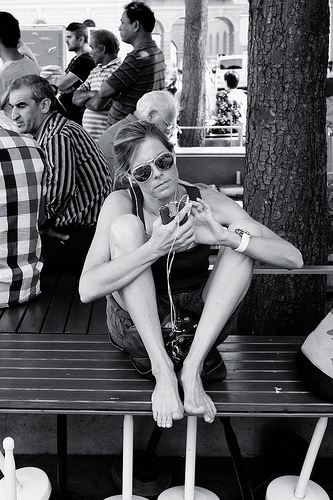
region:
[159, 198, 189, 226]
A mobile cell phone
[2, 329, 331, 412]
A large slatted bench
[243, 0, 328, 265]
A large tree trunk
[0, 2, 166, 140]
A large crowd of standing people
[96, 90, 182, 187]
A older man sitting down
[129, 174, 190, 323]
A cell phone ear piece and cord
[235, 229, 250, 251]
A wristwatch with a white band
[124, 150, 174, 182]
Large rimmed dark sunglasses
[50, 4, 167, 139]
Men standing with their arms folded in front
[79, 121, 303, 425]
A woman sitting on a bench looking at her cell phone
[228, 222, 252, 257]
shiny white watch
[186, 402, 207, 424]
woman's curled up toe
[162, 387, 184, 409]
veins on woman's foot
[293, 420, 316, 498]
long white stand with base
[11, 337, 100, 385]
wooden seating surface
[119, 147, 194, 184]
shiny black sun glasses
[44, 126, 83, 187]
long sleeve black and white shirt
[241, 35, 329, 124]
wide trunk of tree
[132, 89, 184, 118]
old man's silver hair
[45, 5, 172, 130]
men standing around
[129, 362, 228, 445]
bare feet up on the bench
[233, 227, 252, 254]
watch on the woman's arm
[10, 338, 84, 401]
wooden slatted bench around a tree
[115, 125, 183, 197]
woman wearing sunglasses sitting on a bench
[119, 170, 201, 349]
woman listening to music through headphones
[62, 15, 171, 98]
men standing with arms folded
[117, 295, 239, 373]
purse between the woman's legs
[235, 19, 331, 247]
tree surrounded by a bench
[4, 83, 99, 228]
older man in striped shirt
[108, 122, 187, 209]
woman with her hair pulled back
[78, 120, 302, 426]
the woman sitting on a bench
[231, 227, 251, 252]
the watch on the woman's wrist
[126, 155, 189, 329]
the earphones in the woman's ears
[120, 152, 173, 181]
the sunglasses on the woman's face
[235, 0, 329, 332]
the tree trunk next to the woman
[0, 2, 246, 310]
the people behind the woman sitting down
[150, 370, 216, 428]
the woman's bare feet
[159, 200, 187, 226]
the electronic device in the woman's hands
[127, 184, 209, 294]
the tank top on the woman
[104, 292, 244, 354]
the shorts on the woman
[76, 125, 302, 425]
woman sitting on a bench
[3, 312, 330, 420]
wooden bench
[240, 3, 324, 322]
tree trunk next to the woman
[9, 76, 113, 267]
old man in striped shirt sitting down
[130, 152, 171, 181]
sunglasses on the woman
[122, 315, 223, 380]
the woman's purse under her legs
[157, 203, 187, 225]
the woman's cell phone in her hands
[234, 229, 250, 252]
the woman's watch with a white band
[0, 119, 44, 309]
person with plaid shirt sitting